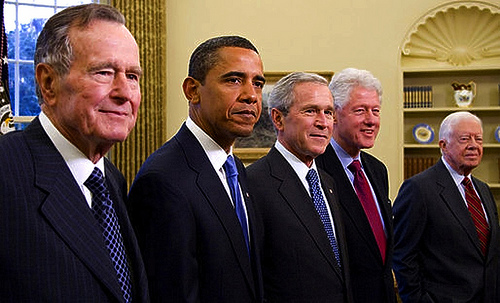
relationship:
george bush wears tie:
[1, 4, 148, 302] [84, 168, 131, 303]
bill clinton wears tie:
[316, 67, 394, 302] [348, 161, 386, 267]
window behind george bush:
[4, 0, 101, 129] [1, 4, 148, 302]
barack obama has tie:
[128, 35, 266, 302] [222, 157, 250, 259]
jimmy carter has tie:
[389, 110, 500, 302] [462, 178, 490, 259]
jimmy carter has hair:
[389, 110, 500, 302] [440, 110, 482, 154]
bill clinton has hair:
[316, 67, 394, 302] [328, 66, 382, 109]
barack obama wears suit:
[128, 35, 266, 302] [126, 121, 265, 302]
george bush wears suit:
[244, 71, 352, 302] [244, 142, 353, 302]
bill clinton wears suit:
[316, 67, 394, 302] [317, 142, 394, 302]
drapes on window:
[93, 1, 166, 195] [4, 0, 101, 129]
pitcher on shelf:
[450, 80, 476, 109] [403, 105, 500, 112]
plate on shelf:
[410, 124, 434, 143] [404, 143, 500, 148]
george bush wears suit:
[1, 4, 148, 302] [0, 111, 150, 301]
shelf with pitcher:
[403, 105, 500, 112] [450, 80, 476, 109]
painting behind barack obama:
[233, 70, 335, 162] [128, 35, 266, 302]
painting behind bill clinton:
[233, 70, 335, 162] [316, 67, 394, 302]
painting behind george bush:
[233, 70, 335, 162] [244, 71, 352, 302]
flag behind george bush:
[0, 0, 17, 135] [1, 4, 148, 302]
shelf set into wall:
[403, 105, 500, 112] [166, 0, 499, 277]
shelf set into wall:
[404, 143, 500, 148] [166, 0, 499, 277]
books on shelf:
[404, 84, 433, 108] [403, 105, 500, 112]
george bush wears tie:
[244, 71, 352, 302] [306, 169, 341, 267]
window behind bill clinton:
[4, 0, 101, 129] [316, 67, 394, 302]